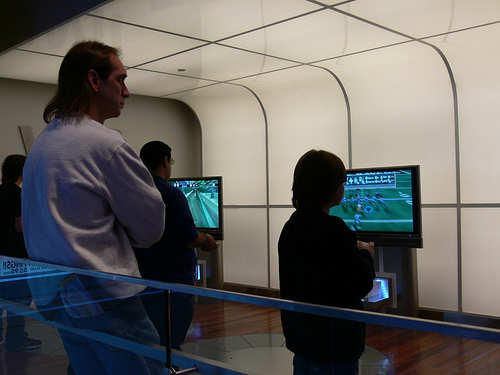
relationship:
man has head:
[20, 40, 178, 373] [53, 32, 135, 125]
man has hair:
[20, 40, 178, 373] [42, 41, 95, 124]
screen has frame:
[181, 175, 223, 232] [204, 173, 229, 241]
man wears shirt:
[20, 40, 178, 373] [22, 115, 165, 303]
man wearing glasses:
[138, 135, 226, 345] [168, 158, 178, 167]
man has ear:
[20, 40, 178, 373] [86, 70, 98, 89]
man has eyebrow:
[20, 40, 178, 373] [113, 72, 127, 79]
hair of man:
[4, 152, 26, 178] [11, 139, 27, 231]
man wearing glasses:
[138, 135, 226, 345] [155, 151, 180, 166]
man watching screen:
[138, 135, 226, 345] [328, 165, 422, 247]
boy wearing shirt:
[279, 152, 388, 372] [279, 211, 371, 351]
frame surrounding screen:
[342, 163, 422, 248] [335, 168, 417, 238]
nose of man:
[121, 82, 132, 99] [20, 40, 178, 373]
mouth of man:
[103, 95, 130, 115] [20, 40, 178, 373]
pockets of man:
[35, 278, 129, 347] [20, 40, 178, 373]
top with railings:
[62, 269, 364, 374] [2, 251, 483, 371]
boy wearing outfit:
[277, 148, 378, 374] [274, 210, 377, 372]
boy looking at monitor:
[277, 148, 378, 374] [319, 117, 423, 242]